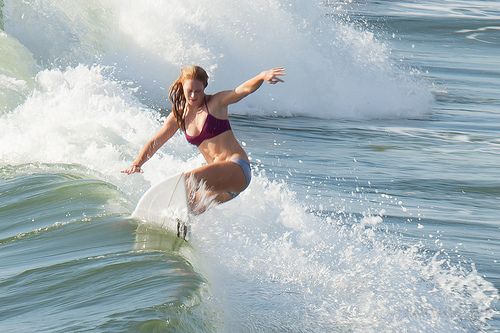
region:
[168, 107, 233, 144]
Woman's purple bikini top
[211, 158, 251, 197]
Woman's blue bikini bottom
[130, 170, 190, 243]
White surfboard in the ocean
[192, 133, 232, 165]
Woman's stomach muscles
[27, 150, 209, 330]
Wave crashing in the ocean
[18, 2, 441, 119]
Wave spraying in the ocean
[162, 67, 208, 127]
Woman's wet red hair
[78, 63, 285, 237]
Woman on a white surfboard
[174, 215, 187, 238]
Black symbol on a surfboard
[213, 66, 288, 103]
Woman's left arm extended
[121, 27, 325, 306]
a woman is surfing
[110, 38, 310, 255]
the woman is wearing her panties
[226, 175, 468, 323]
the water is splashing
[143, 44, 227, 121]
the woman has long hair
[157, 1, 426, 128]
the waves are white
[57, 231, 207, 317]
the water is greenish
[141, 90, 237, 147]
the top is burgundy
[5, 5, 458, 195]
The water is rough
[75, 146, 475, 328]
The water is white and blue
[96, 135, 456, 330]
The water is wet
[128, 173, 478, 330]
The water is splashing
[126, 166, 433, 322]
The water is vicious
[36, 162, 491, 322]
The water is rugged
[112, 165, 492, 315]
The water is tempestuous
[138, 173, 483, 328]
The water is fervent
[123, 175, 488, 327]
The water is tumultuous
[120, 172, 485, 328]
The water is boisterous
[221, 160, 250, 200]
light blue swim pants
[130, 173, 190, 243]
white surf board in water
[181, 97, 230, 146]
redish purple bikini swim top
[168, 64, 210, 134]
woman has red hair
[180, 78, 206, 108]
she is looking down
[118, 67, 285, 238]
woman on a surf board catching waves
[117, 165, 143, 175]
womans hand facing down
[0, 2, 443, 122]
large splash caused by a wave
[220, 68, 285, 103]
her arm is helping her balance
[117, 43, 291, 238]
the women on the surfboard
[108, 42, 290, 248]
the surfer in the water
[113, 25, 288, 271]
the surfer rides the wave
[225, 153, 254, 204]
the blue bikini bottoms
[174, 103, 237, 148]
the red bikini top on the surfer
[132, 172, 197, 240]
the white tip of the board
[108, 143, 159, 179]
the water splashing under the womens hand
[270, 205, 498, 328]
the white water waves splashing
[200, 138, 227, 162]
the abs on the womens stomach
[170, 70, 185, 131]
the long hair over the womens shoulder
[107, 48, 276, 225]
A woman surfing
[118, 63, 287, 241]
young woman riding on surfboard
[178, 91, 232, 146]
woman's burgundy bikini top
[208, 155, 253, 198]
woman's blue bikini bottoms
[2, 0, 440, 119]
ocean spray from crashing wave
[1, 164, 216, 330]
blue-green crest of wave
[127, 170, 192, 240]
white surfboard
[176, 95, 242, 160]
woman's toned torso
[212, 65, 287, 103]
woman's outstretched left arm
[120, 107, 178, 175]
woman's outstretched right arm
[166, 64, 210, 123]
woman's head with wet red hair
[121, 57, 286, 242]
A woman wearing a purple bikini top.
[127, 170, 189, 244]
A white surfboard on waves.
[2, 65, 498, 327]
A white wave on the ocean.